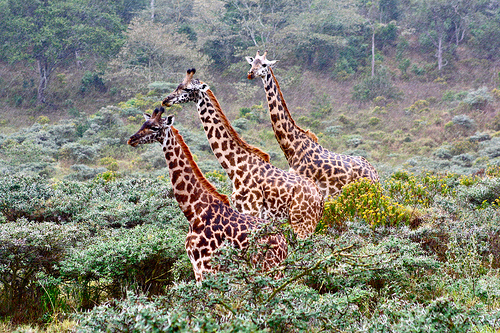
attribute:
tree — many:
[367, 15, 397, 81]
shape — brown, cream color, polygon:
[208, 221, 225, 233]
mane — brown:
[269, 79, 324, 149]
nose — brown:
[247, 67, 254, 79]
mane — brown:
[267, 63, 322, 145]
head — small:
[158, 61, 213, 114]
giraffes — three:
[124, 49, 387, 286]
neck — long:
[124, 49, 296, 209]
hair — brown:
[153, 142, 236, 186]